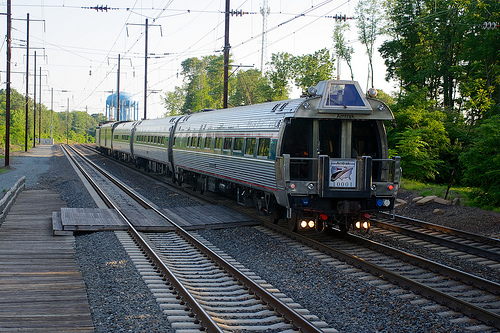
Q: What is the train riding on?
A: Railroad tracks.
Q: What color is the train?
A: Gray.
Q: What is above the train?
A: Electric lines.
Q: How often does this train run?
A: Twice a week.